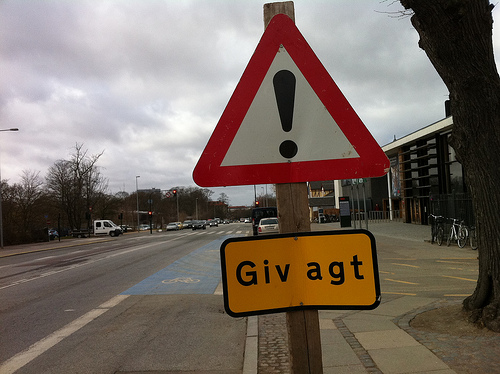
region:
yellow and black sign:
[216, 230, 388, 315]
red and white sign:
[188, 10, 395, 190]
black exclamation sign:
[270, 67, 301, 158]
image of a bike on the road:
[158, 273, 203, 285]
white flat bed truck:
[64, 216, 126, 236]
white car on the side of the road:
[253, 216, 283, 236]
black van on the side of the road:
[247, 205, 279, 233]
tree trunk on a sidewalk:
[393, 2, 498, 342]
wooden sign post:
[257, 0, 332, 372]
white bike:
[447, 214, 468, 249]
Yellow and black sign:
[222, 229, 387, 324]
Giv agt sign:
[207, 223, 394, 312]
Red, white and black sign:
[194, 5, 399, 197]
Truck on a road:
[52, 210, 127, 237]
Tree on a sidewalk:
[374, 0, 498, 327]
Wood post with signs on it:
[235, 11, 349, 372]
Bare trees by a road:
[11, 158, 218, 233]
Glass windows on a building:
[361, 120, 478, 237]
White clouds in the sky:
[14, 10, 246, 188]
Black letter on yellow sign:
[233, 246, 259, 296]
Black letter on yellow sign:
[256, 256, 277, 288]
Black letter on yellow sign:
[270, 256, 291, 287]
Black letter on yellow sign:
[299, 253, 322, 284]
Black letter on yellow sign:
[324, 253, 349, 295]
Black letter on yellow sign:
[343, 249, 364, 292]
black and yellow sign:
[200, 229, 399, 328]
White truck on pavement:
[69, 213, 128, 242]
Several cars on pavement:
[164, 214, 226, 234]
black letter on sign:
[236, 257, 260, 291]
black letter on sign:
[256, 255, 272, 287]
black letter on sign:
[272, 263, 292, 283]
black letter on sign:
[308, 262, 322, 284]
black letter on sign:
[326, 258, 346, 290]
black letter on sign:
[349, 252, 367, 287]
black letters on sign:
[233, 258, 294, 290]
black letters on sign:
[304, 250, 364, 291]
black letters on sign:
[233, 251, 364, 291]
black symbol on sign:
[267, 67, 306, 163]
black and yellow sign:
[193, 203, 388, 325]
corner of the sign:
[191, 221, 248, 288]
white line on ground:
[51, 282, 131, 372]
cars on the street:
[133, 201, 234, 267]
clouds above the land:
[50, 3, 193, 119]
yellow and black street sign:
[220, 227, 393, 312]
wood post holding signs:
[257, 1, 322, 356]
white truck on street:
[80, 211, 125, 236]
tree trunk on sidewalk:
[392, 5, 492, 325]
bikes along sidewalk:
[420, 205, 470, 246]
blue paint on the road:
[106, 230, 236, 290]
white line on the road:
[15, 290, 126, 365]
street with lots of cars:
[0, 217, 264, 363]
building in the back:
[296, 106, 461, 242]